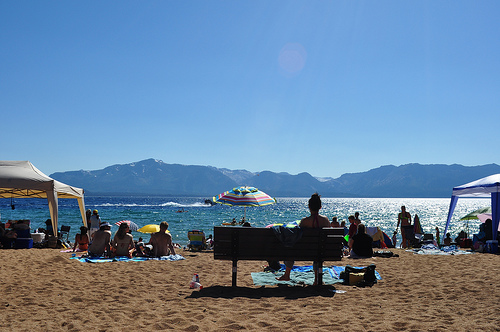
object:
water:
[3, 198, 493, 245]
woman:
[276, 194, 331, 286]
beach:
[0, 248, 499, 331]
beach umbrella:
[213, 184, 276, 207]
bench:
[213, 227, 345, 285]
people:
[88, 221, 116, 258]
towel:
[69, 255, 183, 264]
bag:
[341, 263, 377, 284]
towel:
[251, 266, 381, 284]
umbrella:
[116, 219, 140, 233]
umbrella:
[137, 223, 170, 233]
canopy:
[439, 174, 499, 245]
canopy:
[1, 159, 88, 234]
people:
[444, 232, 456, 244]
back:
[213, 227, 342, 261]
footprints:
[0, 250, 499, 331]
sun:
[328, 195, 492, 210]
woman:
[348, 223, 375, 258]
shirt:
[351, 233, 373, 256]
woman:
[395, 206, 412, 248]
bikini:
[399, 213, 411, 229]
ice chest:
[16, 236, 33, 248]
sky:
[1, 0, 499, 183]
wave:
[104, 201, 214, 209]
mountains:
[48, 157, 499, 199]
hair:
[309, 193, 322, 210]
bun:
[311, 194, 322, 202]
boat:
[205, 198, 218, 204]